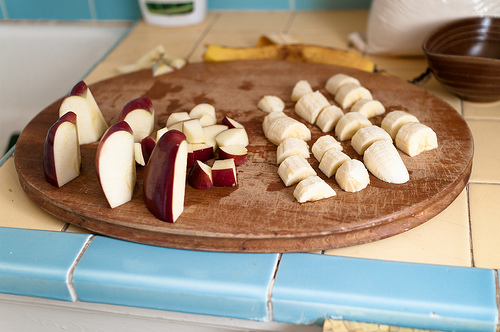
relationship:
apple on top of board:
[43, 111, 80, 187] [15, 60, 474, 253]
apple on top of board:
[212, 159, 237, 185] [15, 60, 474, 253]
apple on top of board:
[224, 116, 242, 127] [15, 60, 474, 253]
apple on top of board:
[187, 160, 212, 188] [15, 60, 474, 253]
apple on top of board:
[185, 119, 205, 144] [15, 60, 474, 253]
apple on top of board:
[141, 138, 156, 163] [15, 60, 474, 253]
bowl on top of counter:
[423, 16, 500, 102] [0, 10, 499, 332]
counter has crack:
[0, 10, 499, 332] [408, 66, 433, 86]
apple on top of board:
[143, 130, 188, 223] [15, 60, 474, 253]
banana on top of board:
[278, 157, 316, 186] [15, 60, 474, 253]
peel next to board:
[203, 35, 375, 71] [15, 60, 474, 253]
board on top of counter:
[15, 60, 474, 253] [0, 10, 499, 332]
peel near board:
[203, 35, 375, 71] [15, 60, 474, 253]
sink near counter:
[0, 21, 132, 166] [0, 10, 499, 332]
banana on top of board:
[312, 136, 342, 161] [15, 60, 474, 253]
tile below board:
[1, 155, 66, 232] [15, 60, 474, 253]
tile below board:
[322, 183, 474, 269] [15, 60, 474, 253]